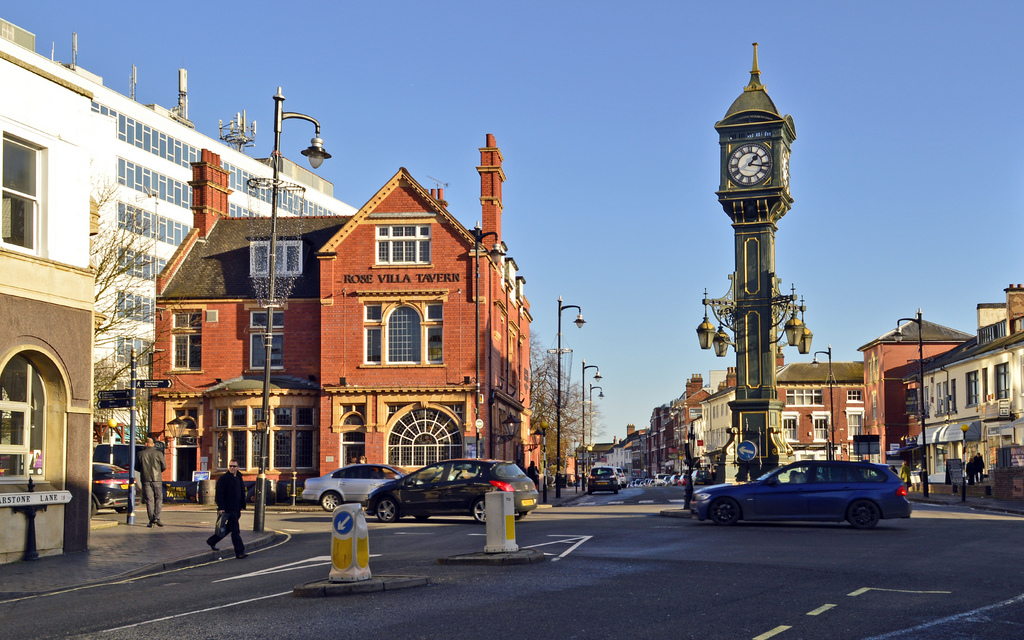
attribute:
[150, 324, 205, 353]
window — glass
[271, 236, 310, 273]
window — glass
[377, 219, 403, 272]
window — glass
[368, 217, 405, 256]
window — glass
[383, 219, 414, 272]
window — glass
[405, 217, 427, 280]
window — glass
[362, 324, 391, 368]
window — glass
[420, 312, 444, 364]
window — glass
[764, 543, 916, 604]
lines — white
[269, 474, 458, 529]
sign — blue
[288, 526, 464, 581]
curb — grey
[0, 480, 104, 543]
sign — white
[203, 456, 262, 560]
man — walking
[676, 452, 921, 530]
car — BLUE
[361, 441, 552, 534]
car — BLACK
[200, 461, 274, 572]
man — WALKING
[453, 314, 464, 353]
brick — RED 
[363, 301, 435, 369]
window — ARCHED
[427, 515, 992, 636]
street — BLUE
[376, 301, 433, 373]
window — glass 